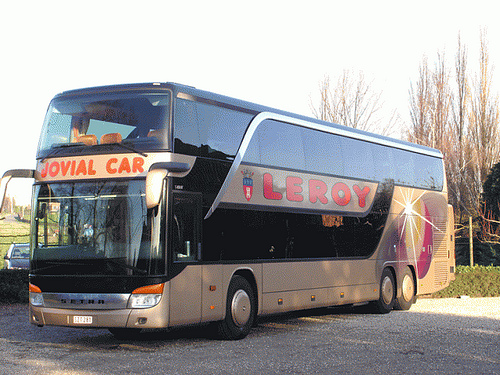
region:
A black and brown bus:
[20, 77, 465, 345]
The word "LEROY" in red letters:
[256, 167, 375, 214]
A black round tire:
[212, 271, 261, 345]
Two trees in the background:
[312, 26, 497, 214]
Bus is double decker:
[21, 70, 460, 346]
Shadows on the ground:
[2, 303, 499, 373]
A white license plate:
[68, 310, 95, 330]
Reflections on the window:
[54, 183, 163, 271]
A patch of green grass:
[422, 264, 498, 298]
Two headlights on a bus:
[22, 275, 167, 310]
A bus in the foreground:
[15, 71, 470, 346]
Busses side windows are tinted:
[171, 100, 443, 269]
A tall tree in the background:
[308, 25, 498, 248]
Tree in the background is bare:
[300, 25, 498, 244]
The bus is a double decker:
[10, 83, 465, 338]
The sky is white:
[6, 0, 493, 192]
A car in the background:
[3, 235, 48, 274]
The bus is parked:
[18, 69, 463, 343]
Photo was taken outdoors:
[7, 29, 498, 364]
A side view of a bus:
[165, 83, 472, 350]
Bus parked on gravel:
[26, 89, 456, 327]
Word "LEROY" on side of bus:
[263, 171, 374, 207]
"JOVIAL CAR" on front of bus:
[40, 151, 152, 181]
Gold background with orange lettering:
[42, 152, 143, 182]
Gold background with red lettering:
[260, 175, 370, 207]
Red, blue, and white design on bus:
[235, 168, 257, 203]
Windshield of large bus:
[32, 198, 146, 253]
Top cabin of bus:
[45, 94, 319, 159]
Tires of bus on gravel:
[370, 263, 420, 318]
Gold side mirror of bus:
[140, 162, 173, 216]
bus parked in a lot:
[9, 66, 486, 344]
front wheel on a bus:
[208, 264, 266, 344]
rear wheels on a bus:
[371, 260, 424, 317]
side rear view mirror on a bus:
[138, 158, 193, 213]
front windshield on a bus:
[22, 172, 177, 269]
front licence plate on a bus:
[65, 312, 99, 330]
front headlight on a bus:
[124, 279, 171, 314]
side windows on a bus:
[233, 110, 450, 197]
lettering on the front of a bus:
[38, 148, 150, 185]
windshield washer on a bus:
[21, 255, 93, 278]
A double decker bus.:
[14, 83, 471, 350]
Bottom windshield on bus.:
[27, 180, 165, 277]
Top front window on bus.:
[42, 86, 173, 152]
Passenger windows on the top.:
[171, 90, 444, 175]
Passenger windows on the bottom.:
[208, 180, 393, 269]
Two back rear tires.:
[375, 255, 420, 317]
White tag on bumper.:
[68, 312, 100, 324]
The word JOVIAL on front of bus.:
[30, 155, 102, 182]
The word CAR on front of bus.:
[103, 155, 148, 177]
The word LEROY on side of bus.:
[259, 162, 369, 214]